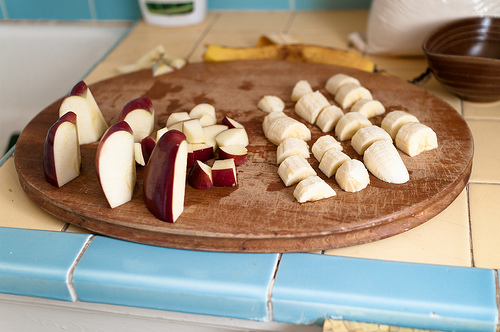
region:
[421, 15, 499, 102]
A brown bowl on counter.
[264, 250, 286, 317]
A crack in the counter top.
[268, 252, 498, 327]
A blue tile on the counter.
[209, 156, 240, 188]
A square chopped piece of apple.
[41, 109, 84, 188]
A red apple slice.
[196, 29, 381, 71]
A yellow banana peel.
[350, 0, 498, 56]
A white plastic bag.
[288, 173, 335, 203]
A slice of banana.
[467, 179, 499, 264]
A white tile on the counter.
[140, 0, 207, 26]
A white and green bottle.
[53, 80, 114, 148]
The apple chunk is unpeeled.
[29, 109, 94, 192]
The apple chunk is unpeeled.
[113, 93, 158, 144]
The apple chunk is unpeeled.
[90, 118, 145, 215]
The apple chunk is unpeeled.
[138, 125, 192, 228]
The apple chunk is unpeeled.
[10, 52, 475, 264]
Apple and banana chunks on a cutting board.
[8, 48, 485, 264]
The cutting board is round.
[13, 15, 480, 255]
Banana peeling lies next to the cutting board.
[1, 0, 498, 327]
The countertop is tile.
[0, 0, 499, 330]
The tile is blue and cream colored.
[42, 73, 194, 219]
slices of apple with red peel standing upright on cutting board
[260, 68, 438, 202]
small slices of banana lined up on cutting board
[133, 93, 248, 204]
chopped pieces of apple on cutting board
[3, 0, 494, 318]
white tile bordered by blue tile covering counter top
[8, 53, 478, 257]
round wooden cutting board on counter top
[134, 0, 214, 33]
white plastic bottle of soap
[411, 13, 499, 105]
brown pottery bowl in corner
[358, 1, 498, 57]
clear bag of flour behind bowl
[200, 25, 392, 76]
empty banana peel laying near cutting board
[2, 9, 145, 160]
white porcelain sink near counter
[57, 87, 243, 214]
apple slices on board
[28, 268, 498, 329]
blue trim on counter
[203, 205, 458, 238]
board made of wood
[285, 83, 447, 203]
small slices of banana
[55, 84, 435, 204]
banana and apples on plate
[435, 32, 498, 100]
brown bowl in back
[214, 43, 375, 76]
two banana skins by board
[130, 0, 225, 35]
bottle in the background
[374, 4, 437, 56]
bag of white substance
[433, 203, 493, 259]
tile under board is white